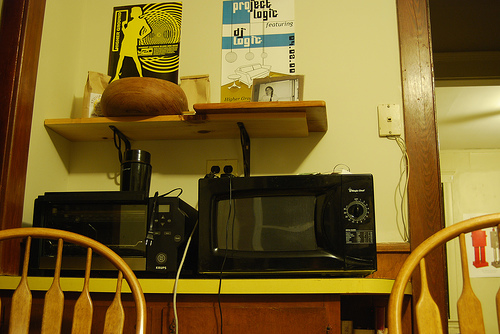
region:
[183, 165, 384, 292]
A black microwave oven.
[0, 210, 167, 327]
A wooden chair in a kitchen.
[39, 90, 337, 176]
A wooden shelf on a wall.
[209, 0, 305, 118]
a sign on a wall.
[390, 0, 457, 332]
a long wooden door frame.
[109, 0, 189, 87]
A picture on a wall.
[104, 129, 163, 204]
a cup full of writing utensils.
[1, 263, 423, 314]
a table with items on it.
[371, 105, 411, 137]
a outlet on a wall.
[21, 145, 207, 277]
a microwave oven.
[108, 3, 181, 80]
A yellow and black poster on the wall.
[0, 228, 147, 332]
The back of a chair.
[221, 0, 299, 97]
A colorful poster on the wall.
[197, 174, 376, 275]
A black microwave on the counter.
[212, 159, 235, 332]
A black cord plugged in.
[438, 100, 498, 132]
A shadow on the ceiling.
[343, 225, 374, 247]
Writing on the microwave.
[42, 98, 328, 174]
A brown shelf on the wall.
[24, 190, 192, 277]
A black toaster oven.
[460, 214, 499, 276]
A white poster with designs.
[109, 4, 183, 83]
yellow graphic poster with female figure on it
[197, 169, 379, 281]
a microwave oven with large number dial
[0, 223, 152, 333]
back of goldenrod chair with 4 slats showing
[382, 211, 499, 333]
back of golderod chair with 2 slats showing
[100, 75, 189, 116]
rounded wooden bowl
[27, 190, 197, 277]
black toaster oven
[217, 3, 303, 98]
poster with blue and black detail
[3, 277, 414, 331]
kitchen cabinet with yellow countertop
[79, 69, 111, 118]
small apper bag with white label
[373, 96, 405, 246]
beige wall plate with wires hanging out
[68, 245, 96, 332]
wooden brown chair slat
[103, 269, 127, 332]
wooden brown chair slat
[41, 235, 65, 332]
wooden brown chair slat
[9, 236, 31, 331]
wooden brown chair slat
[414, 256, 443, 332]
wooden brown chair slat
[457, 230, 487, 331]
wooden brown chair slat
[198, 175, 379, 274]
black colored unplugged mircowave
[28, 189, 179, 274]
black colored unplugged mircowave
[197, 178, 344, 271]
black colored microwave door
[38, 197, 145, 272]
black colored microwave door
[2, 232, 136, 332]
A wooden arm chair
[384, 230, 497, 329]
A wooden arm chair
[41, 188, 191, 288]
A black electric microwave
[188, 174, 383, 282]
A black electric microwave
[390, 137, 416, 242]
A white socket extention wire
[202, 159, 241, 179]
A white kitchen socket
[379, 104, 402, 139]
A white wall socket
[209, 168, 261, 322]
A black socket extention wire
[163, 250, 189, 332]
A white socket extention wire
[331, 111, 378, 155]
A beige kitchen wall